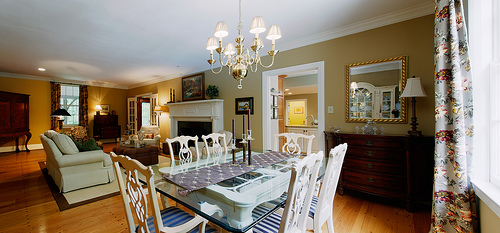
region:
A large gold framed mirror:
[343, 54, 412, 130]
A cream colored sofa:
[27, 126, 131, 206]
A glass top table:
[125, 135, 330, 230]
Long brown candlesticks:
[217, 105, 252, 145]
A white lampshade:
[396, 76, 428, 102]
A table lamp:
[397, 71, 432, 138]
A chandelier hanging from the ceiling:
[209, 1, 282, 81]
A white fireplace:
[157, 98, 224, 153]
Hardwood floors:
[6, 141, 476, 231]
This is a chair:
[99, 145, 160, 223]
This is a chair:
[158, 125, 203, 196]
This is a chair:
[202, 123, 237, 187]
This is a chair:
[268, 110, 316, 177]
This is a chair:
[325, 122, 355, 229]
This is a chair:
[264, 140, 325, 229]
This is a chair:
[155, 120, 207, 192]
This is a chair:
[199, 118, 239, 182]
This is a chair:
[104, 145, 167, 232]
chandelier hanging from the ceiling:
[199, 0, 279, 82]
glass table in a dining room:
[122, 139, 328, 227]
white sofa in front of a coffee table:
[45, 133, 119, 184]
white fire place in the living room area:
[166, 97, 223, 142]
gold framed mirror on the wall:
[345, 56, 410, 124]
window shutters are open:
[126, 94, 163, 131]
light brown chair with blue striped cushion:
[105, 148, 205, 231]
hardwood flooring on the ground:
[0, 149, 427, 230]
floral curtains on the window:
[428, 0, 472, 227]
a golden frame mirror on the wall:
[343, 53, 408, 125]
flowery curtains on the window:
[429, 1, 476, 231]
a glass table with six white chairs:
[112, 128, 346, 231]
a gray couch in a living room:
[40, 127, 121, 204]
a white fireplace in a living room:
[168, 100, 225, 140]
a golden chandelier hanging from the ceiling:
[206, 3, 282, 88]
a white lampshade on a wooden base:
[401, 75, 426, 134]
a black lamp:
[53, 108, 70, 130]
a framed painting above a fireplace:
[180, 70, 206, 99]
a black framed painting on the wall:
[233, 95, 253, 115]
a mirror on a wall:
[340, 56, 413, 124]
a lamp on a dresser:
[395, 73, 434, 143]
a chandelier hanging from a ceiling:
[199, 0, 292, 92]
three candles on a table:
[225, 103, 259, 171]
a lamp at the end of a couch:
[47, 105, 74, 136]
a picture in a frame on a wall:
[176, 71, 209, 104]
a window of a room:
[58, 81, 85, 130]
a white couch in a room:
[38, 125, 120, 208]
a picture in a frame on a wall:
[230, 92, 259, 117]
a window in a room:
[462, 0, 497, 215]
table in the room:
[131, 93, 341, 221]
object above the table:
[170, 23, 300, 103]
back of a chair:
[91, 132, 188, 231]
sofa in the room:
[14, 120, 126, 215]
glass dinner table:
[142, 140, 349, 227]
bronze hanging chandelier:
[200, 5, 300, 95]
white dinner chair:
[105, 153, 189, 232]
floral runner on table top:
[166, 148, 322, 183]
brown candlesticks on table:
[224, 111, 256, 166]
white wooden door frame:
[255, 60, 330, 185]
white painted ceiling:
[3, 3, 443, 88]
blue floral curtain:
[427, 5, 488, 230]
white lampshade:
[394, 72, 427, 109]